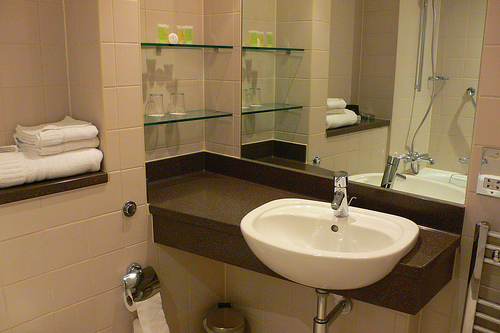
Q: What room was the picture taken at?
A: It was taken at the bathroom.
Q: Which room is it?
A: It is a bathroom.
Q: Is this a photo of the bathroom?
A: Yes, it is showing the bathroom.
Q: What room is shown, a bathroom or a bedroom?
A: It is a bathroom.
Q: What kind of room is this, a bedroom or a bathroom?
A: It is a bathroom.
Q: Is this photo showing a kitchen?
A: No, the picture is showing a bathroom.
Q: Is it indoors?
A: Yes, it is indoors.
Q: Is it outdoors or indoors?
A: It is indoors.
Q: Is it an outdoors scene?
A: No, it is indoors.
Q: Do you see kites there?
A: No, there are no kites.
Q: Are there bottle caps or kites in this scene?
A: No, there are no kites or bottle caps.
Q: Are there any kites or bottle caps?
A: No, there are no kites or bottle caps.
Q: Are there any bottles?
A: No, there are no bottles.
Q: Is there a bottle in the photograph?
A: No, there are no bottles.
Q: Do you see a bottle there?
A: No, there are no bottles.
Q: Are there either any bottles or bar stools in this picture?
A: No, there are no bottles or bar stools.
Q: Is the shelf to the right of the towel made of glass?
A: Yes, the shelf is made of glass.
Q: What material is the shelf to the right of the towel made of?
A: The shelf is made of glass.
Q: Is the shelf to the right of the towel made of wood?
A: No, the shelf is made of glass.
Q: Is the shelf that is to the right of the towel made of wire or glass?
A: The shelf is made of glass.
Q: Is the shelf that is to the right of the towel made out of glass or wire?
A: The shelf is made of glass.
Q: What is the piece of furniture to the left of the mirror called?
A: The piece of furniture is a shelf.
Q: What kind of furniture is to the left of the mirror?
A: The piece of furniture is a shelf.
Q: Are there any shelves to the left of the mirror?
A: Yes, there is a shelf to the left of the mirror.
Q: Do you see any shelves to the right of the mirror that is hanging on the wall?
A: No, the shelf is to the left of the mirror.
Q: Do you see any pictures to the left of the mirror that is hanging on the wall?
A: No, there is a shelf to the left of the mirror.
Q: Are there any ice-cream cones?
A: No, there are no ice-cream cones.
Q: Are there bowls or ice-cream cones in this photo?
A: No, there are no ice-cream cones or bowls.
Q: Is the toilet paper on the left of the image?
A: Yes, the toilet paper is on the left of the image.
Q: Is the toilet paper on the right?
A: No, the toilet paper is on the left of the image.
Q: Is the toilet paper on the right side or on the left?
A: The toilet paper is on the left of the image.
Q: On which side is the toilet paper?
A: The toilet paper is on the left of the image.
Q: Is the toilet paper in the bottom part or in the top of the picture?
A: The toilet paper is in the bottom of the image.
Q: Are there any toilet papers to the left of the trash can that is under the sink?
A: Yes, there is a toilet paper to the left of the garbage bin.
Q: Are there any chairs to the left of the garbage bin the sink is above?
A: No, there is a toilet paper to the left of the trashcan.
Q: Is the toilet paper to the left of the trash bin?
A: Yes, the toilet paper is to the left of the trash bin.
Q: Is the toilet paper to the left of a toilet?
A: No, the toilet paper is to the left of the trash bin.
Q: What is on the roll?
A: The toilet paper is on the toilet roll.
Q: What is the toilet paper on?
A: The toilet paper is on the toilet roll.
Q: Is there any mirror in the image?
A: Yes, there is a mirror.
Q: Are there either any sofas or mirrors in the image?
A: Yes, there is a mirror.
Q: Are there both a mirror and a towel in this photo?
A: Yes, there are both a mirror and a towel.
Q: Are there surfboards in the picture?
A: No, there are no surfboards.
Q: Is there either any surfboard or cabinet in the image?
A: No, there are no surfboards or cabinets.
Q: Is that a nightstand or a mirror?
A: That is a mirror.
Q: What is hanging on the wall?
A: The mirror is hanging on the wall.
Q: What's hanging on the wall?
A: The mirror is hanging on the wall.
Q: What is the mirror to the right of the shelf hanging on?
A: The mirror is hanging on the wall.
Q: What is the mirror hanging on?
A: The mirror is hanging on the wall.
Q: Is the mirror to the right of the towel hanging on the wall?
A: Yes, the mirror is hanging on the wall.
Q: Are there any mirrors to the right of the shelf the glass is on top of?
A: Yes, there is a mirror to the right of the shelf.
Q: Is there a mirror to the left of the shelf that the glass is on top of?
A: No, the mirror is to the right of the shelf.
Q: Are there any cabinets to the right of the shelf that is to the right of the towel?
A: No, there is a mirror to the right of the shelf.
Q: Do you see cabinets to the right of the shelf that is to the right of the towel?
A: No, there is a mirror to the right of the shelf.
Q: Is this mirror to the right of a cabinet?
A: No, the mirror is to the right of a shelf.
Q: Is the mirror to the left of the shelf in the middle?
A: No, the mirror is to the right of the shelf.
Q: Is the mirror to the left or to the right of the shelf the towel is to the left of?
A: The mirror is to the right of the shelf.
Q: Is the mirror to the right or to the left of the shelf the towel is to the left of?
A: The mirror is to the right of the shelf.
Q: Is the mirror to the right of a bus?
A: No, the mirror is to the right of the towel.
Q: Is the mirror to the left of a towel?
A: No, the mirror is to the right of a towel.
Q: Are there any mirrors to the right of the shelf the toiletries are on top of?
A: Yes, there is a mirror to the right of the shelf.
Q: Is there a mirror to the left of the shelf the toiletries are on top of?
A: No, the mirror is to the right of the shelf.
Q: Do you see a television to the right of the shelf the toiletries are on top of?
A: No, there is a mirror to the right of the shelf.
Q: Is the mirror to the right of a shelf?
A: Yes, the mirror is to the right of a shelf.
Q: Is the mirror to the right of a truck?
A: No, the mirror is to the right of a shelf.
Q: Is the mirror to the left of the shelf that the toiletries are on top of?
A: No, the mirror is to the right of the shelf.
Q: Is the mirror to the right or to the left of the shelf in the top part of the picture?
A: The mirror is to the right of the shelf.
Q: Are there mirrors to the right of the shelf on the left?
A: Yes, there is a mirror to the right of the shelf.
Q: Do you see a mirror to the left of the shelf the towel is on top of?
A: No, the mirror is to the right of the shelf.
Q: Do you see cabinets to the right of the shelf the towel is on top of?
A: No, there is a mirror to the right of the shelf.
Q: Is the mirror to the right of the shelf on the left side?
A: Yes, the mirror is to the right of the shelf.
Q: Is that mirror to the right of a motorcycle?
A: No, the mirror is to the right of the shelf.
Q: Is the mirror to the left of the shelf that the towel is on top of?
A: No, the mirror is to the right of the shelf.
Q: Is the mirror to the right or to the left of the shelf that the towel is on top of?
A: The mirror is to the right of the shelf.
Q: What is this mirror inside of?
A: The mirror is inside the bathroom.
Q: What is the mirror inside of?
A: The mirror is inside the bathroom.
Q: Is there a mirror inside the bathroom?
A: Yes, there is a mirror inside the bathroom.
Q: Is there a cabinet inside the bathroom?
A: No, there is a mirror inside the bathroom.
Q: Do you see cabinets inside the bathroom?
A: No, there is a mirror inside the bathroom.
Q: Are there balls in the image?
A: No, there are no balls.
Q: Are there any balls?
A: No, there are no balls.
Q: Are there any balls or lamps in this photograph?
A: No, there are no balls or lamps.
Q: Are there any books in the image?
A: No, there are no books.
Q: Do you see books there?
A: No, there are no books.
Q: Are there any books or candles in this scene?
A: No, there are no books or candles.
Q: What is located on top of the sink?
A: The faucet is on top of the sink.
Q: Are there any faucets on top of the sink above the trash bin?
A: Yes, there is a faucet on top of the sink.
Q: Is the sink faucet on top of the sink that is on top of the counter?
A: Yes, the faucet is on top of the sink.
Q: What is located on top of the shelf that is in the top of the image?
A: The toiletries are on top of the shelf.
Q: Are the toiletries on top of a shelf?
A: Yes, the toiletries are on top of a shelf.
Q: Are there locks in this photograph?
A: No, there are no locks.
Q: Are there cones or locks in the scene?
A: No, there are no locks or cones.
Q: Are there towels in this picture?
A: Yes, there is a towel.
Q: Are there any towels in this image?
A: Yes, there is a towel.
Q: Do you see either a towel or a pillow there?
A: Yes, there is a towel.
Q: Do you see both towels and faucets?
A: Yes, there are both a towel and a faucet.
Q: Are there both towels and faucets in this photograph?
A: Yes, there are both a towel and a faucet.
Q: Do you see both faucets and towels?
A: Yes, there are both a towel and a faucet.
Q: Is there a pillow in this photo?
A: No, there are no pillows.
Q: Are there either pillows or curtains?
A: No, there are no pillows or curtains.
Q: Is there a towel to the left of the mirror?
A: Yes, there is a towel to the left of the mirror.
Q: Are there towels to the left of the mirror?
A: Yes, there is a towel to the left of the mirror.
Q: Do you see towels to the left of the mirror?
A: Yes, there is a towel to the left of the mirror.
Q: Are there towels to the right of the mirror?
A: No, the towel is to the left of the mirror.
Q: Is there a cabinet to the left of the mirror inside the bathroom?
A: No, there is a towel to the left of the mirror.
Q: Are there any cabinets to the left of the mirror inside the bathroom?
A: No, there is a towel to the left of the mirror.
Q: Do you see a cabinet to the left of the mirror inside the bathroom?
A: No, there is a towel to the left of the mirror.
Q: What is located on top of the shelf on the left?
A: The towel is on top of the shelf.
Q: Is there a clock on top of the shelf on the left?
A: No, there is a towel on top of the shelf.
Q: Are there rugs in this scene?
A: No, there are no rugs.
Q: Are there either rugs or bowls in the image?
A: No, there are no rugs or bowls.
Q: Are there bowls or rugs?
A: No, there are no rugs or bowls.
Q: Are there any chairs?
A: No, there are no chairs.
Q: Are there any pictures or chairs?
A: No, there are no chairs or pictures.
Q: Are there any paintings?
A: No, there are no paintings.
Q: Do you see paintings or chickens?
A: No, there are no paintings or chickens.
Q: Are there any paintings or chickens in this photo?
A: No, there are no paintings or chickens.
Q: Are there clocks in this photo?
A: No, there are no clocks.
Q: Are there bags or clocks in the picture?
A: No, there are no clocks or bags.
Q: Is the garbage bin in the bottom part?
A: Yes, the garbage bin is in the bottom of the image.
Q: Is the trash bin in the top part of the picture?
A: No, the trash bin is in the bottom of the image.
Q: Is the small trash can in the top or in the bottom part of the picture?
A: The trashcan is in the bottom of the image.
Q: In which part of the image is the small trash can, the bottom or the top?
A: The trashcan is in the bottom of the image.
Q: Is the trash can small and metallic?
A: Yes, the trash can is small and metallic.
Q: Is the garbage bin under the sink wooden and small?
A: No, the garbage can is small but metallic.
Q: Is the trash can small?
A: Yes, the trash can is small.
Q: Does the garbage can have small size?
A: Yes, the garbage can is small.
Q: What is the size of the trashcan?
A: The trashcan is small.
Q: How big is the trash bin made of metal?
A: The garbage can is small.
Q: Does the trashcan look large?
A: No, the trashcan is small.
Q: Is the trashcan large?
A: No, the trashcan is small.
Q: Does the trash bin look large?
A: No, the trash bin is small.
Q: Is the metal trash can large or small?
A: The garbage bin is small.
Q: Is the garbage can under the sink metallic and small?
A: Yes, the trash can is metallic and small.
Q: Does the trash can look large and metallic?
A: No, the trash can is metallic but small.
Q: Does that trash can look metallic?
A: Yes, the trash can is metallic.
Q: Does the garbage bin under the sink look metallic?
A: Yes, the trashcan is metallic.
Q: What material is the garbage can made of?
A: The garbage can is made of metal.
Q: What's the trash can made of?
A: The garbage can is made of metal.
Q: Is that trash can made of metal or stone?
A: The trash can is made of metal.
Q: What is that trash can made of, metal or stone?
A: The trash can is made of metal.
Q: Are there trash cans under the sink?
A: Yes, there is a trash can under the sink.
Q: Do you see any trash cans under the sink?
A: Yes, there is a trash can under the sink.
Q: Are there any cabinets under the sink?
A: No, there is a trash can under the sink.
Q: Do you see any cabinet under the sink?
A: No, there is a trash can under the sink.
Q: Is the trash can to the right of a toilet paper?
A: Yes, the trash can is to the right of a toilet paper.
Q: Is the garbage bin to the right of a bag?
A: No, the garbage bin is to the right of a toilet paper.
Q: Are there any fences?
A: No, there are no fences.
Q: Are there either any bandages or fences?
A: No, there are no fences or bandages.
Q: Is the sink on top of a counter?
A: Yes, the sink is on top of a counter.